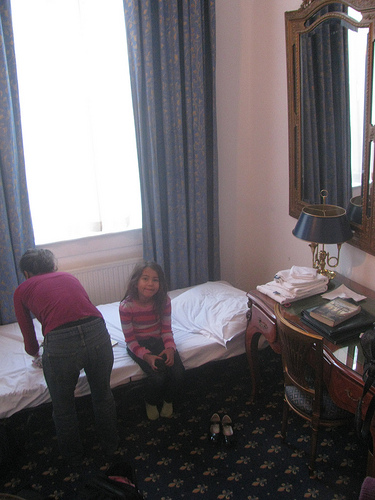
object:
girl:
[117, 256, 187, 427]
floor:
[2, 342, 375, 499]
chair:
[273, 307, 365, 464]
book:
[308, 284, 362, 328]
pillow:
[167, 273, 263, 350]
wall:
[209, 1, 373, 298]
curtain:
[2, 0, 38, 323]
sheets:
[0, 280, 254, 419]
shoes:
[203, 404, 238, 450]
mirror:
[282, 0, 374, 258]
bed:
[0, 274, 252, 416]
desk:
[237, 267, 374, 429]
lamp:
[293, 200, 351, 291]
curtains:
[122, 0, 223, 295]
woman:
[12, 247, 116, 477]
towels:
[288, 266, 330, 284]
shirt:
[117, 295, 175, 359]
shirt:
[12, 266, 105, 357]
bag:
[76, 457, 147, 498]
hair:
[120, 255, 170, 314]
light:
[10, 1, 148, 245]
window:
[8, 0, 157, 246]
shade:
[289, 200, 355, 245]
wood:
[244, 271, 373, 470]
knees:
[146, 363, 163, 382]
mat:
[6, 339, 374, 494]